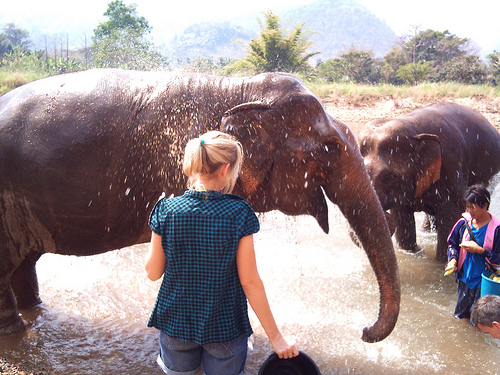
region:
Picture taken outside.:
[34, 3, 485, 334]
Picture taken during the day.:
[44, 13, 486, 284]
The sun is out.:
[32, 3, 430, 87]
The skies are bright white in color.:
[61, 16, 498, 33]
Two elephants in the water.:
[51, 39, 496, 300]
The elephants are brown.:
[55, 48, 473, 199]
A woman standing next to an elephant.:
[115, 36, 282, 344]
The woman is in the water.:
[114, 145, 331, 355]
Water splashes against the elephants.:
[105, 65, 469, 256]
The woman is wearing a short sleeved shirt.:
[112, 179, 234, 361]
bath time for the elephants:
[13, 40, 499, 370]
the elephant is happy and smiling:
[215, 71, 402, 345]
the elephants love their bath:
[11, 54, 499, 371]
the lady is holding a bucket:
[142, 130, 319, 372]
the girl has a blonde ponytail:
[183, 126, 240, 196]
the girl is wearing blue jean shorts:
[155, 335, 250, 373]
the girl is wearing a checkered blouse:
[145, 187, 250, 342]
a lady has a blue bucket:
[441, 185, 496, 330]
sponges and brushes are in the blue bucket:
[475, 260, 496, 302]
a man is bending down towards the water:
[469, 291, 499, 361]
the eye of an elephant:
[314, 133, 339, 157]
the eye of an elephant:
[382, 161, 398, 184]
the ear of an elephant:
[409, 124, 446, 201]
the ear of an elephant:
[220, 92, 280, 188]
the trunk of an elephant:
[316, 157, 418, 356]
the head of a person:
[168, 120, 247, 202]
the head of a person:
[457, 173, 492, 222]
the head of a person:
[225, 225, 300, 361]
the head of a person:
[140, 220, 172, 282]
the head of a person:
[432, 218, 456, 272]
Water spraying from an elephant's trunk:
[232, 65, 433, 338]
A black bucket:
[255, 342, 315, 369]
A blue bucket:
[475, 265, 498, 302]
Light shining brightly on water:
[269, 232, 341, 319]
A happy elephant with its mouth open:
[216, 69, 357, 237]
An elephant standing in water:
[348, 99, 481, 260]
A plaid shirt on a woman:
[135, 178, 253, 329]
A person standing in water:
[445, 183, 492, 326]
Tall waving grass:
[341, 83, 387, 105]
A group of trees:
[374, 23, 468, 75]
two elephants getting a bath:
[1, 0, 499, 374]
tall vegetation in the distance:
[0, 1, 497, 70]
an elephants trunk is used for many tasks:
[321, 163, 413, 343]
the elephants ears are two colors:
[413, 133, 443, 191]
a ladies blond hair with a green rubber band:
[183, 131, 241, 175]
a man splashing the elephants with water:
[468, 294, 498, 341]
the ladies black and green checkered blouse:
[146, 191, 258, 337]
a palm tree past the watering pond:
[235, 6, 321, 73]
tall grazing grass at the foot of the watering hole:
[320, 81, 497, 102]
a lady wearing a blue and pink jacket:
[446, 213, 498, 278]